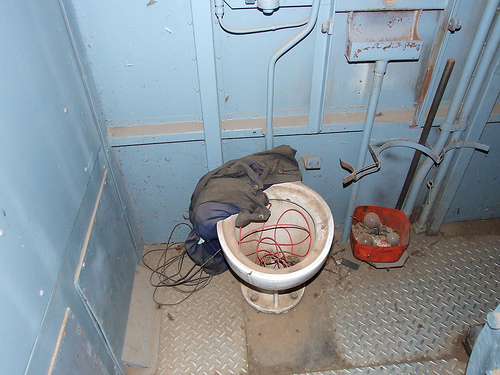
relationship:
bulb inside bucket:
[384, 227, 402, 248] [352, 201, 416, 253]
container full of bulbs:
[349, 204, 411, 262] [361, 211, 383, 227]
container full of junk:
[349, 204, 411, 262] [351, 210, 399, 247]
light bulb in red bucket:
[362, 212, 384, 228] [349, 200, 412, 267]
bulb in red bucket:
[384, 227, 402, 248] [349, 200, 412, 267]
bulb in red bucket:
[356, 231, 374, 247] [349, 200, 412, 267]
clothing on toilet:
[178, 142, 308, 282] [217, 180, 335, 316]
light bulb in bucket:
[362, 212, 384, 228] [341, 197, 416, 266]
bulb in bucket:
[379, 227, 406, 248] [341, 197, 416, 266]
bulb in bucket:
[354, 229, 374, 249] [341, 197, 416, 266]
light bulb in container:
[362, 212, 384, 228] [349, 204, 411, 262]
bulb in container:
[384, 227, 402, 248] [349, 204, 411, 262]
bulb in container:
[356, 231, 374, 247] [349, 204, 411, 262]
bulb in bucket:
[356, 231, 374, 247] [346, 192, 413, 268]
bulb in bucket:
[384, 227, 402, 248] [346, 192, 413, 268]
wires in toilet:
[238, 209, 311, 268] [217, 180, 335, 316]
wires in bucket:
[229, 199, 316, 269] [220, 167, 329, 309]